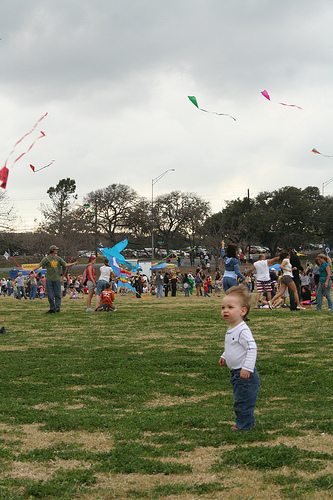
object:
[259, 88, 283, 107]
kite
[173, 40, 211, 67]
sky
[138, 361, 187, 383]
grass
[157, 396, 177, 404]
dirt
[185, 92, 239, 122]
kites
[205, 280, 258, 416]
toddler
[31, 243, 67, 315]
man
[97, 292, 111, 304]
shirt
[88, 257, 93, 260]
headband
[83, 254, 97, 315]
woman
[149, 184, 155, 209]
post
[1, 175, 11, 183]
sign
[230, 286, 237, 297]
hair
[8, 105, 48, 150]
tail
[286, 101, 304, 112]
tails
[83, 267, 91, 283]
tank top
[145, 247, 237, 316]
people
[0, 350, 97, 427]
field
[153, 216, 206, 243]
trees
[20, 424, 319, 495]
dirt